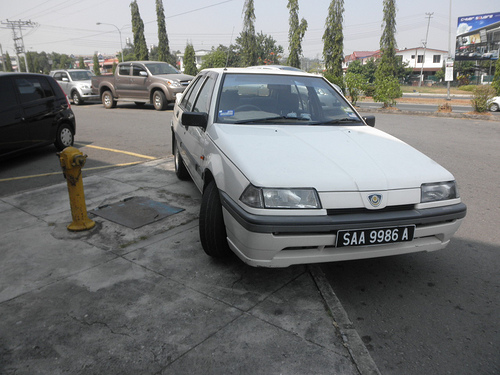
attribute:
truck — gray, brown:
[97, 60, 190, 105]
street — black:
[88, 107, 162, 150]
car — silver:
[62, 68, 95, 99]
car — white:
[180, 68, 457, 274]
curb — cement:
[100, 163, 190, 312]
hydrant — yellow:
[53, 146, 100, 236]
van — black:
[4, 73, 76, 147]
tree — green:
[376, 8, 404, 88]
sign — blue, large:
[460, 18, 496, 58]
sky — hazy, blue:
[182, 11, 240, 38]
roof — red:
[356, 51, 375, 58]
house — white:
[402, 48, 444, 82]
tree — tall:
[324, 1, 341, 67]